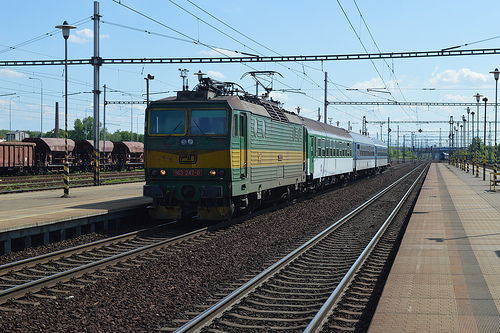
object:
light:
[209, 169, 217, 176]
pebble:
[341, 247, 346, 252]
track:
[164, 160, 431, 333]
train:
[143, 80, 392, 223]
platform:
[366, 162, 499, 332]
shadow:
[426, 232, 500, 242]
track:
[1, 213, 234, 299]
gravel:
[47, 292, 167, 330]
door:
[238, 112, 248, 180]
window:
[232, 114, 239, 137]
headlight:
[159, 170, 167, 176]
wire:
[327, 0, 421, 128]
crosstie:
[281, 269, 349, 279]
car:
[304, 118, 355, 190]